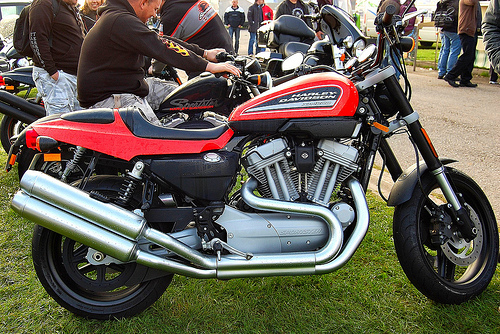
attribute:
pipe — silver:
[7, 164, 376, 281]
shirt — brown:
[81, 28, 151, 100]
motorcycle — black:
[20, 11, 495, 323]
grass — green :
[10, 316, 497, 330]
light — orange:
[418, 127, 443, 162]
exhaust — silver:
[10, 165, 216, 279]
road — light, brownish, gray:
[398, 76, 498, 194]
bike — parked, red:
[2, 19, 499, 324]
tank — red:
[226, 71, 363, 131]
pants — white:
[36, 80, 76, 115]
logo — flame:
[151, 33, 191, 60]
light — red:
[26, 128, 63, 158]